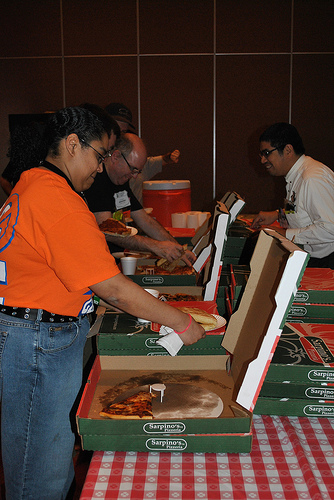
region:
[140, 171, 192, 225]
the cooler is orange and white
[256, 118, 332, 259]
the man is wearing a white shirt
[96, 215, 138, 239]
the pizza is on the plate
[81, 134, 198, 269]
the man is wearing a black shirt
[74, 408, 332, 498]
the tablecloth is red and white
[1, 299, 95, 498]
the man is wearing blue jeans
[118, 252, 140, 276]
the cup is white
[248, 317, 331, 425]
three closed pizza boxes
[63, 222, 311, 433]
the pizza box is open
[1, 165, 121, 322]
the man is wearing an orange shirt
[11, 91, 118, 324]
lady in orange tshirt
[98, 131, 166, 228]
man in black tshirt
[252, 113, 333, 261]
man in white shirt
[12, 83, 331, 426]
five people picking out pizza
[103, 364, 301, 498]
pizza boxes on tablecloth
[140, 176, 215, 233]
orange and white cooler with cups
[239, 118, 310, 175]
man with black hair smiling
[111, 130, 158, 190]
man with glasses smiling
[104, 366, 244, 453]
almost empty pizza box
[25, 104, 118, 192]
woman with black-rimmed glasses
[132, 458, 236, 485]
red and white checker square table cloth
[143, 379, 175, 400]
white pizza divider in box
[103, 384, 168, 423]
slice of meat pizza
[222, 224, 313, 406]
cover of pizza box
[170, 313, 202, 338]
red bracelet on woman's hand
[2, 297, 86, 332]
black stud belt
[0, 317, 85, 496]
blue jeans with pockets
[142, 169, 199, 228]
large orange and white cooler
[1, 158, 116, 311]
woman wearing orange shirt with blue logs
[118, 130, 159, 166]
man's glistening bald head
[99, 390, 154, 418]
Slice of pizza in pizza box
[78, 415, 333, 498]
Red and white checkered table cloth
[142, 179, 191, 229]
Tall red colored cooler with white lid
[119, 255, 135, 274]
white styrofoam cup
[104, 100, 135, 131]
Two tone dark colored hat on mans head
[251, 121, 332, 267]
dark haired man in glasses smiling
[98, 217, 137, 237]
two pieces of pizza on white plate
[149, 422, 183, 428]
White letters that say Sarpino's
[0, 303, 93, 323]
A black belt with small holes in it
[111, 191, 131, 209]
white name tag on mans shirt